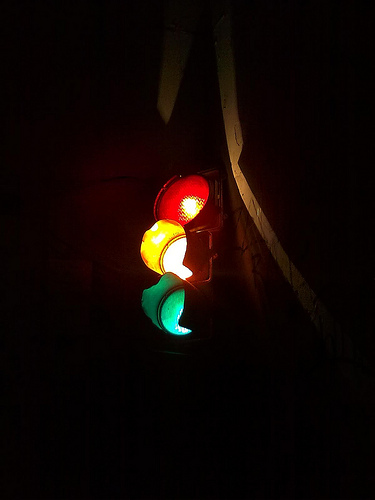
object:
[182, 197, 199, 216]
bulb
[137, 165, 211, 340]
bank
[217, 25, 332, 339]
pole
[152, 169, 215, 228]
light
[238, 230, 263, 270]
metal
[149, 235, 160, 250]
cover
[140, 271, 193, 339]
round shield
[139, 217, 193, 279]
round shield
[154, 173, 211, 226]
round shield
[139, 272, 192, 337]
green light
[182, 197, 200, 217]
center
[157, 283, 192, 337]
circle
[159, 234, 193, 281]
circle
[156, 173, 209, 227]
circle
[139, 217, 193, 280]
light